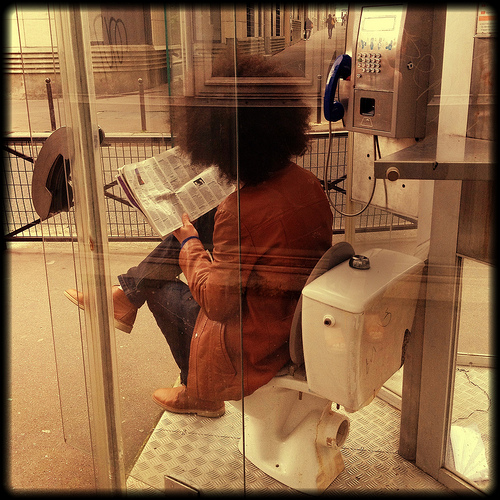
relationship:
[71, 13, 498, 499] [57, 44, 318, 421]
telephone booth behind lady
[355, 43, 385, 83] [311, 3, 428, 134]
buttons on phone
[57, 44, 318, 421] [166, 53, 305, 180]
lady has hair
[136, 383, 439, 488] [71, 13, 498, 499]
floor of telephone booth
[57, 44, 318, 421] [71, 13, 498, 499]
lady seated in telephone booth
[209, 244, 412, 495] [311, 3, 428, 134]
toilet below phone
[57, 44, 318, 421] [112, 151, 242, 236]
lady reading a newspaper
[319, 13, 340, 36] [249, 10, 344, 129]
person walking down sidewalk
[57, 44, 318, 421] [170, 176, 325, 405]
lady wearing jacket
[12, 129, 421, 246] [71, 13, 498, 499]
fence behind telephone booth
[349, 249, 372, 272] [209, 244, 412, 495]
knob on top of toilet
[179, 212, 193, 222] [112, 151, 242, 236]
thumb on top of newspaper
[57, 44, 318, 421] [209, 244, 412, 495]
lady sitting on a toilet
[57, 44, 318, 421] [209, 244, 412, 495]
lady on toilet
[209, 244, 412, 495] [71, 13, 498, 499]
toilet in a telephone booth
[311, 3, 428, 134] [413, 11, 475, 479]
phone on wall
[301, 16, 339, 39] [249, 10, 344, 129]
people on sidewalk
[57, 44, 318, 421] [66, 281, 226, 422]
lady wearing boots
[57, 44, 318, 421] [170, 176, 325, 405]
lady wearing a jacket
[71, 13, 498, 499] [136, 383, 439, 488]
telephone booth with a floor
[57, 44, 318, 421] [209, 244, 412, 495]
lady sitting on toilet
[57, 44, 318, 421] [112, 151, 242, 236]
lady reading newspaper